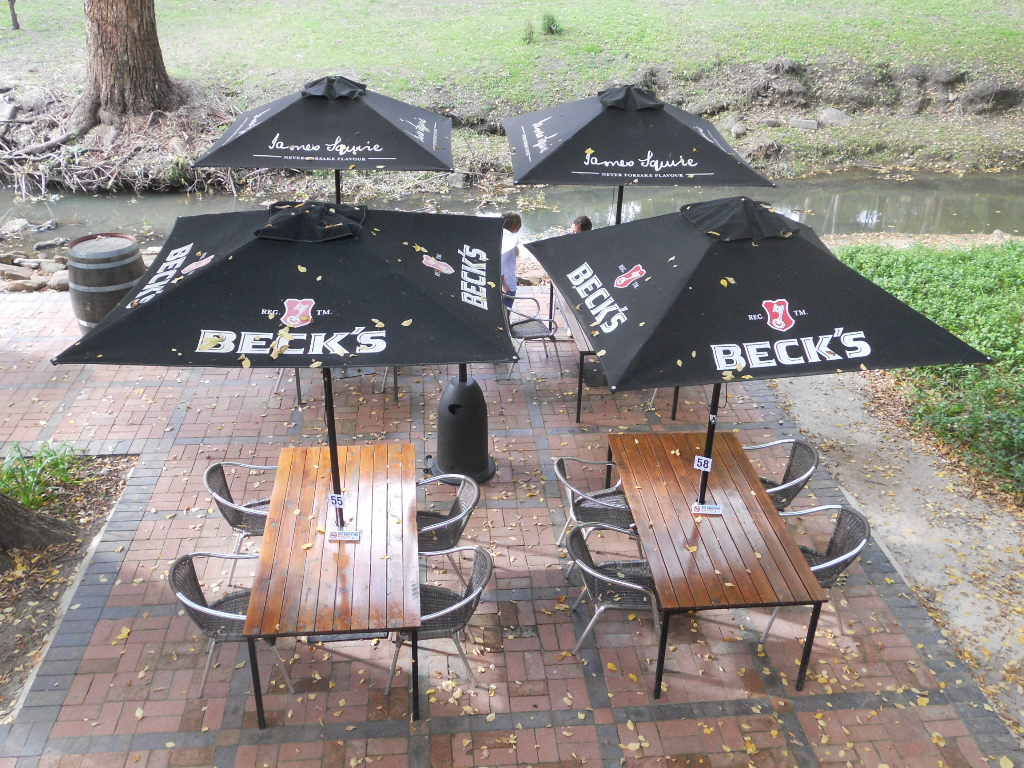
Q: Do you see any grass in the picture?
A: Yes, there is grass.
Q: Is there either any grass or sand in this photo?
A: Yes, there is grass.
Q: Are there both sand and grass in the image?
A: No, there is grass but no sand.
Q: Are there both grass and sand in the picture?
A: No, there is grass but no sand.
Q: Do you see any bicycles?
A: No, there are no bicycles.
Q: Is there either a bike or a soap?
A: No, there are no bikes or soaps.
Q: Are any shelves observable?
A: No, there are no shelves.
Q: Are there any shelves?
A: No, there are no shelves.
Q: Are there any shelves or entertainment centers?
A: No, there are no shelves or entertainment centers.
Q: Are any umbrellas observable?
A: Yes, there is an umbrella.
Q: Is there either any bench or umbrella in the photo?
A: Yes, there is an umbrella.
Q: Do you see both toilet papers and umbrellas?
A: No, there is an umbrella but no toilet papers.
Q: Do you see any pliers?
A: No, there are no pliers.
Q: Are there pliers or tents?
A: No, there are no pliers or tents.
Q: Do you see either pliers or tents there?
A: No, there are no pliers or tents.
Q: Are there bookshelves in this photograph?
A: No, there are no bookshelves.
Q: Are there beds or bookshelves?
A: No, there are no bookshelves or beds.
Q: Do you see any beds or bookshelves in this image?
A: No, there are no bookshelves or beds.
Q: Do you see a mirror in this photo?
A: No, there are no mirrors.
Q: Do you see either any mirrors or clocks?
A: No, there are no mirrors or clocks.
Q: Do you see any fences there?
A: No, there are no fences.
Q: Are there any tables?
A: Yes, there is a table.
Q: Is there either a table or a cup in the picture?
A: Yes, there is a table.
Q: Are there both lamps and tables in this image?
A: No, there is a table but no lamps.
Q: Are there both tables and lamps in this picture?
A: No, there is a table but no lamps.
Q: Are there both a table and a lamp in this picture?
A: No, there is a table but no lamps.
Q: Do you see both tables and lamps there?
A: No, there is a table but no lamps.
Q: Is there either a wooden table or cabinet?
A: Yes, there is a wood table.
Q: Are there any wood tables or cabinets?
A: Yes, there is a wood table.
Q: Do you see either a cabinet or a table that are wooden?
A: Yes, the table is wooden.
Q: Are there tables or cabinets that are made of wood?
A: Yes, the table is made of wood.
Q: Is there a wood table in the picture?
A: Yes, there is a table that is made of wood.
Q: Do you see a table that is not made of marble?
A: Yes, there is a table that is made of wood.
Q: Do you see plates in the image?
A: No, there are no plates.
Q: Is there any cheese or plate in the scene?
A: No, there are no plates or cheese.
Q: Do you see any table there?
A: Yes, there is a table.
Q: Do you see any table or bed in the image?
A: Yes, there is a table.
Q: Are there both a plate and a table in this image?
A: No, there is a table but no plates.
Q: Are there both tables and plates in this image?
A: No, there is a table but no plates.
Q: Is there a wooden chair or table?
A: Yes, there is a wood table.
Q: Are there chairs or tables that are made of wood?
A: Yes, the table is made of wood.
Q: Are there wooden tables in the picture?
A: Yes, there is a wood table.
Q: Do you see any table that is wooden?
A: Yes, there is a table that is wooden.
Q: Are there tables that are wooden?
A: Yes, there is a table that is wooden.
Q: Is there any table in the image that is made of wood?
A: Yes, there is a table that is made of wood.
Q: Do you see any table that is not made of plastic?
A: Yes, there is a table that is made of wood.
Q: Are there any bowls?
A: No, there are no bowls.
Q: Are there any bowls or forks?
A: No, there are no bowls or forks.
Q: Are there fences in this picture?
A: No, there are no fences.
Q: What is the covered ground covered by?
A: The ground is covered by the leaves.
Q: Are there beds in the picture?
A: No, there are no beds.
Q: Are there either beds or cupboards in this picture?
A: No, there are no beds or cupboards.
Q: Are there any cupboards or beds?
A: No, there are no beds or cupboards.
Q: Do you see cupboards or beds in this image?
A: No, there are no beds or cupboards.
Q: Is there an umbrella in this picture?
A: Yes, there is an umbrella.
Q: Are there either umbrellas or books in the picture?
A: Yes, there is an umbrella.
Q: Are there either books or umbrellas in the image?
A: Yes, there is an umbrella.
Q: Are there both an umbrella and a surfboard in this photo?
A: No, there is an umbrella but no surfboards.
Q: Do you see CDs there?
A: No, there are no cds.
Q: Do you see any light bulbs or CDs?
A: No, there are no CDs or light bulbs.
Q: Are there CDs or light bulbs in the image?
A: No, there are no CDs or light bulbs.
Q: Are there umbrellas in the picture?
A: Yes, there is an umbrella.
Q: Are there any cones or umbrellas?
A: Yes, there is an umbrella.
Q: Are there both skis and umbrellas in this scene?
A: No, there is an umbrella but no skis.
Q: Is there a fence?
A: No, there are no fences.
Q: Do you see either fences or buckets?
A: No, there are no fences or buckets.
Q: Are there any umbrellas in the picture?
A: Yes, there is an umbrella.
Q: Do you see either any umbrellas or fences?
A: Yes, there is an umbrella.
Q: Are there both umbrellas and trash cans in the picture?
A: No, there is an umbrella but no trash cans.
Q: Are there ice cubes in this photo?
A: No, there are no ice cubes.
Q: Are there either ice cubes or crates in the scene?
A: No, there are no ice cubes or crates.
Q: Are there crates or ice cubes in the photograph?
A: No, there are no ice cubes or crates.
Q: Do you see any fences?
A: No, there are no fences.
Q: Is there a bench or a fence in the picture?
A: No, there are no fences or benches.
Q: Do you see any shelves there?
A: No, there are no shelves.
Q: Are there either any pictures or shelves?
A: No, there are no shelves or pictures.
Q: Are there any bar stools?
A: No, there are no bar stools.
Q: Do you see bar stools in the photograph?
A: No, there are no bar stools.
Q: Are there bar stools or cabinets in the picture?
A: No, there are no bar stools or cabinets.